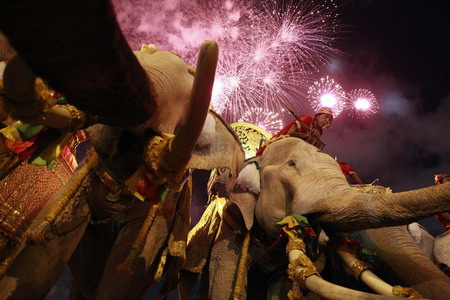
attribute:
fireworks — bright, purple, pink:
[215, 0, 383, 107]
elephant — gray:
[206, 134, 444, 298]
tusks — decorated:
[287, 239, 409, 297]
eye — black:
[285, 160, 298, 168]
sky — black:
[331, 4, 448, 80]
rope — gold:
[229, 231, 252, 299]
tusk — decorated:
[287, 243, 397, 299]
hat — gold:
[313, 105, 334, 121]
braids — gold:
[229, 234, 257, 299]